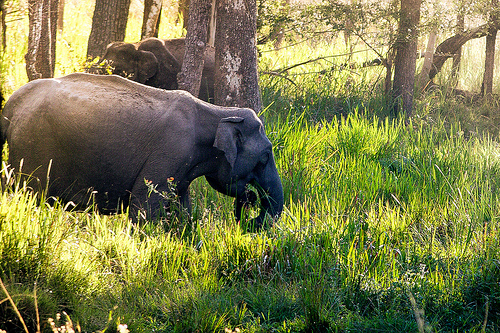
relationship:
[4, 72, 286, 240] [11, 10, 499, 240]
elephant in woods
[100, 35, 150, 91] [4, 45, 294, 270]
head of elephant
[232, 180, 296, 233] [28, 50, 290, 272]
trunk of elephant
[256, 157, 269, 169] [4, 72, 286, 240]
eye of elephant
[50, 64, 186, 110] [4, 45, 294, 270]
back of elephant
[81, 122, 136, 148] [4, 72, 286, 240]
skin of elephant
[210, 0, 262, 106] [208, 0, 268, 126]
trunk of tree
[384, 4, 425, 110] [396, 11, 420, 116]
bark of tree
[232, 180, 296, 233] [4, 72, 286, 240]
trunk of elephant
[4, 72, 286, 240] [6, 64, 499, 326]
elephant in grass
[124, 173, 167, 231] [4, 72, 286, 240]
leg of elephant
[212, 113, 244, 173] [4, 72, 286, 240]
ears of elephant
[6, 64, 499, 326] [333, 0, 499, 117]
grass shaded by tree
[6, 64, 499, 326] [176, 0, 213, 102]
grass shaded by tree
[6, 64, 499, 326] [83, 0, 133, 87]
grass shaded by tree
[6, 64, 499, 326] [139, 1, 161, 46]
grass shaded by tree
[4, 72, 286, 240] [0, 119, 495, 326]
elephant walking throgh grass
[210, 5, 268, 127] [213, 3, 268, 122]
trunk of tree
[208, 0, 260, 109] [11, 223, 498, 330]
tree casting shadows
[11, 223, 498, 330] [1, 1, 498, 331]
shadows on grassy field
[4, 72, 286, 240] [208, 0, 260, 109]
elephant walking through tree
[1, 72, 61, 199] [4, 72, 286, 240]
backside of elephant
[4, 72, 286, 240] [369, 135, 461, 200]
elephant in grass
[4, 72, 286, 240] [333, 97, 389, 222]
elephant in grass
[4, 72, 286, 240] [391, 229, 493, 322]
elephant in grass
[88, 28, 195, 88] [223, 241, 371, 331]
elephant in grass